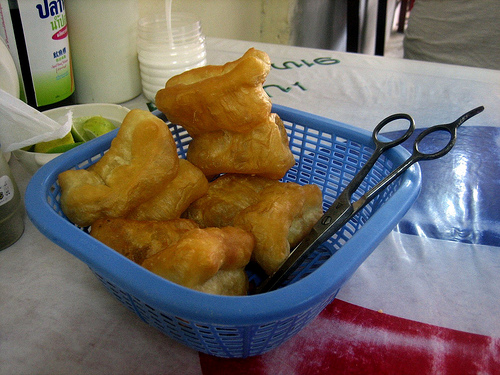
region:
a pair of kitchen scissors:
[278, 100, 483, 290]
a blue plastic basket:
[121, 292, 335, 358]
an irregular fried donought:
[153, 47, 271, 133]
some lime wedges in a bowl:
[69, 109, 109, 139]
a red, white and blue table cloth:
[422, 160, 498, 370]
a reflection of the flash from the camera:
[422, 153, 482, 241]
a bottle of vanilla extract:
[0, 0, 75, 97]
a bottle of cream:
[135, 0, 205, 95]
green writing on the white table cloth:
[270, 53, 340, 98]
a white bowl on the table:
[68, 100, 128, 119]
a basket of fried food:
[16, 42, 470, 351]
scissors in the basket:
[285, 82, 481, 303]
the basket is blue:
[55, 51, 431, 353]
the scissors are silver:
[270, 75, 469, 260]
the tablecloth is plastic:
[363, 85, 495, 352]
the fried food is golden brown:
[111, 37, 309, 269]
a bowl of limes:
[16, 92, 138, 178]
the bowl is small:
[2, 92, 127, 165]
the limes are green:
[11, 96, 119, 155]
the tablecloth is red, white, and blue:
[295, 1, 497, 368]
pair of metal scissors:
[256, 102, 483, 294]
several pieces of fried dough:
[60, 50, 325, 288]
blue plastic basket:
[29, 89, 422, 360]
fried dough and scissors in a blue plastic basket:
[31, 53, 483, 352]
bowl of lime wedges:
[21, 101, 134, 165]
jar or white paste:
[140, 15, 202, 100]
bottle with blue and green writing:
[10, 0, 73, 113]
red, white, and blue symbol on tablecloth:
[196, 127, 496, 369]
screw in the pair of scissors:
[320, 217, 332, 228]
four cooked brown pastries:
[63, 49, 318, 294]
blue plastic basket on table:
[27, 96, 422, 356]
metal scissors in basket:
[257, 103, 482, 300]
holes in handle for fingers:
[373, 112, 460, 159]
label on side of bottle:
[10, 1, 73, 107]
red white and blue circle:
[199, 123, 496, 373]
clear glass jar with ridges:
[138, 10, 204, 102]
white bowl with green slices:
[16, 102, 131, 173]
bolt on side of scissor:
[319, 213, 333, 228]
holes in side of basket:
[280, 120, 394, 239]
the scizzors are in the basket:
[320, 97, 463, 207]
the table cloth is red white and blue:
[447, 164, 488, 365]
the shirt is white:
[421, 17, 490, 59]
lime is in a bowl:
[78, 115, 108, 137]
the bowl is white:
[18, 152, 38, 170]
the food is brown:
[130, 45, 288, 249]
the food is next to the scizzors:
[18, 49, 479, 374]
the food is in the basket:
[15, 32, 428, 339]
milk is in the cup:
[134, 7, 214, 59]